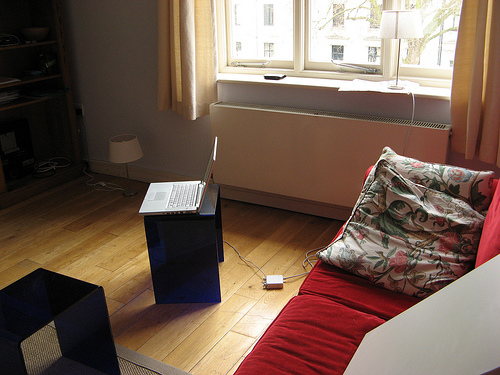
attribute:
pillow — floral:
[344, 146, 495, 225]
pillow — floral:
[319, 163, 487, 297]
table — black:
[136, 217, 243, 304]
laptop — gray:
[117, 127, 223, 218]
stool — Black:
[6, 264, 124, 358]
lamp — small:
[373, 4, 431, 95]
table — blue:
[119, 125, 235, 315]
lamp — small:
[366, 12, 412, 97]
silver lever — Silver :
[333, 52, 387, 79]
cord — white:
[230, 230, 360, 315]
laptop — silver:
[133, 134, 223, 216]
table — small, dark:
[15, 257, 69, 349]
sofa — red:
[234, 165, 497, 373]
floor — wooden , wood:
[2, 167, 343, 373]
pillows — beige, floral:
[361, 141, 473, 305]